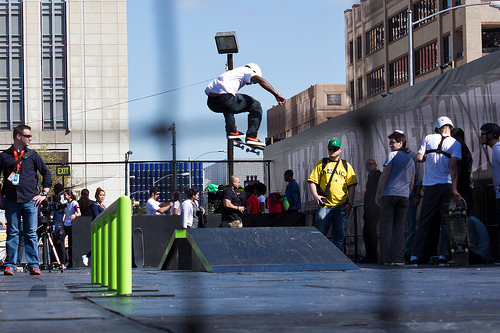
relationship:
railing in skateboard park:
[88, 192, 135, 298] [2, 55, 499, 332]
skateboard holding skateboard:
[447, 190, 471, 268] [447, 190, 471, 268]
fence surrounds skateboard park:
[6, 154, 276, 275] [2, 55, 499, 332]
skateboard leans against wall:
[134, 227, 147, 268] [132, 212, 186, 269]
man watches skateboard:
[308, 139, 360, 259] [230, 136, 267, 154]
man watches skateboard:
[1, 122, 54, 278] [230, 136, 267, 154]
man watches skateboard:
[373, 130, 417, 270] [230, 136, 267, 154]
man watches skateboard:
[362, 156, 386, 264] [230, 136, 267, 154]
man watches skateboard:
[477, 121, 499, 217] [230, 136, 267, 154]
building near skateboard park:
[343, 1, 499, 114] [2, 55, 499, 332]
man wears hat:
[308, 139, 360, 259] [326, 136, 344, 151]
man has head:
[308, 139, 360, 259] [327, 137, 345, 162]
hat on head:
[326, 136, 344, 151] [327, 137, 345, 162]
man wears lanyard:
[1, 122, 54, 278] [12, 146, 27, 173]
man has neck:
[1, 122, 54, 278] [9, 143, 29, 153]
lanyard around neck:
[12, 146, 27, 173] [9, 143, 29, 153]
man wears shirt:
[308, 139, 360, 259] [307, 157, 362, 207]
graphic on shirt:
[320, 168, 348, 178] [307, 157, 362, 207]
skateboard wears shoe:
[230, 136, 267, 154] [246, 134, 270, 151]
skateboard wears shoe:
[230, 136, 267, 154] [226, 129, 250, 140]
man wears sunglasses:
[308, 139, 360, 259] [327, 146, 342, 152]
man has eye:
[308, 139, 360, 259] [327, 147, 332, 152]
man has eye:
[308, 139, 360, 259] [333, 147, 339, 153]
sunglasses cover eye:
[327, 146, 342, 152] [327, 147, 332, 152]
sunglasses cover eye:
[327, 146, 342, 152] [333, 147, 339, 153]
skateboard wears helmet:
[230, 136, 267, 154] [245, 61, 263, 78]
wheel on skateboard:
[446, 207, 456, 220] [447, 190, 471, 268]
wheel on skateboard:
[461, 207, 467, 217] [447, 190, 471, 268]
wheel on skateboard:
[449, 247, 456, 258] [447, 190, 471, 268]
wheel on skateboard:
[463, 245, 472, 256] [447, 190, 471, 268]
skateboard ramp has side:
[158, 226, 362, 273] [157, 228, 189, 273]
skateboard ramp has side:
[158, 226, 362, 273] [187, 226, 360, 272]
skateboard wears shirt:
[230, 136, 267, 154] [204, 65, 257, 98]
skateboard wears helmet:
[447, 190, 471, 268] [432, 115, 454, 135]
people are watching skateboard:
[307, 113, 500, 269] [230, 136, 267, 154]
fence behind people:
[6, 154, 276, 275] [209, 165, 303, 228]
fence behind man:
[6, 154, 276, 275] [1, 122, 54, 276]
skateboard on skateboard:
[230, 136, 267, 154] [230, 138, 266, 156]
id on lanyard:
[6, 169, 20, 185] [12, 146, 27, 173]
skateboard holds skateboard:
[447, 190, 471, 268] [447, 190, 471, 268]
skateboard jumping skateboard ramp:
[230, 136, 267, 154] [158, 226, 362, 273]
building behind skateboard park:
[0, 1, 130, 207] [2, 55, 499, 332]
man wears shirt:
[1, 122, 54, 278] [2, 147, 54, 205]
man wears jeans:
[1, 122, 54, 278] [2, 199, 44, 270]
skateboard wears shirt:
[447, 190, 471, 268] [418, 132, 464, 188]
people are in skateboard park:
[209, 165, 303, 228] [2, 55, 499, 332]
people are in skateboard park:
[307, 113, 500, 269] [2, 55, 499, 332]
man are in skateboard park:
[1, 122, 54, 276] [2, 55, 499, 332]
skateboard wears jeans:
[230, 136, 267, 154] [206, 91, 264, 138]